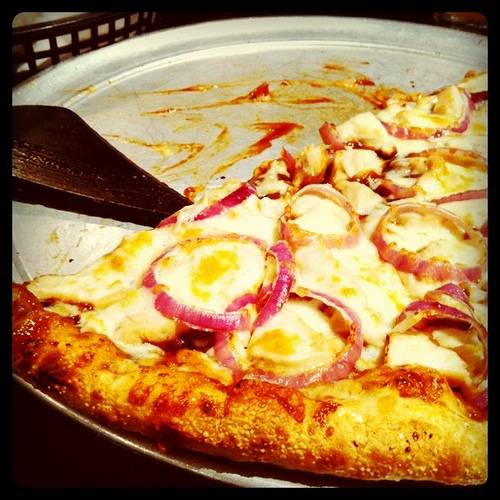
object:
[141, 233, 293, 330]
onion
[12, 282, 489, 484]
crust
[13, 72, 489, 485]
cheese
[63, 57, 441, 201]
sauce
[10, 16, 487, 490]
pan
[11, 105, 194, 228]
pizza server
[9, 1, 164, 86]
basket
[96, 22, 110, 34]
hole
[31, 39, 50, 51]
hole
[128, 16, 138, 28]
hole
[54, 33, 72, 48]
hole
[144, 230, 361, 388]
onions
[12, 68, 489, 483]
mozzarella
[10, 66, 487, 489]
pizza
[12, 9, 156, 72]
paper